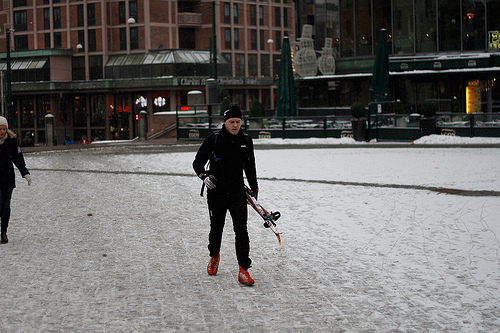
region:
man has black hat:
[218, 100, 244, 119]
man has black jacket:
[199, 124, 268, 199]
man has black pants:
[196, 193, 258, 265]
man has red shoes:
[199, 248, 254, 291]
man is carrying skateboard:
[205, 166, 302, 234]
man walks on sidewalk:
[179, 111, 308, 303]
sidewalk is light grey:
[59, 150, 191, 292]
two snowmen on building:
[272, 31, 354, 83]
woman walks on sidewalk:
[0, 122, 42, 269]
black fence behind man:
[197, 102, 393, 147]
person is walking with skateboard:
[212, 106, 297, 280]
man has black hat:
[219, 107, 252, 117]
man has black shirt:
[184, 118, 252, 231]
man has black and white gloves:
[181, 136, 253, 198]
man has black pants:
[201, 180, 263, 241]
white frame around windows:
[43, 1, 263, 51]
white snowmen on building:
[285, 30, 355, 74]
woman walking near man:
[1, 101, 16, 218]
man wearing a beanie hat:
[219, 103, 246, 143]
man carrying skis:
[244, 182, 286, 253]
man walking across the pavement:
[169, 89, 296, 307]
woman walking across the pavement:
[0, 108, 41, 251]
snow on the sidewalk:
[416, 128, 490, 156]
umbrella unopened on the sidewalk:
[270, 31, 307, 128]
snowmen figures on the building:
[289, 23, 343, 85]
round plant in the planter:
[345, 100, 374, 143]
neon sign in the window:
[111, 98, 136, 122]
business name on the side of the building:
[179, 77, 256, 91]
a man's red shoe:
[237, 266, 259, 286]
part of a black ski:
[242, 178, 283, 223]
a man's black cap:
[220, 101, 250, 123]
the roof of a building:
[105, 50, 227, 68]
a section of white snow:
[255, 143, 498, 190]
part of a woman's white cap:
[0, 116, 10, 126]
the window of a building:
[85, 27, 97, 51]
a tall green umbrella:
[275, 33, 298, 116]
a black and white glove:
[199, 170, 221, 190]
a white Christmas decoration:
[292, 20, 319, 77]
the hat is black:
[210, 100, 247, 120]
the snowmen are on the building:
[287, 13, 339, 75]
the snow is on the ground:
[64, 194, 148, 302]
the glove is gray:
[199, 167, 216, 196]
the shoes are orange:
[196, 249, 267, 300]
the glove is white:
[21, 172, 35, 186]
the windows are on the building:
[222, 2, 266, 49]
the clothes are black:
[192, 133, 261, 248]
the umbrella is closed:
[363, 16, 395, 101]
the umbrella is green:
[272, 21, 299, 119]